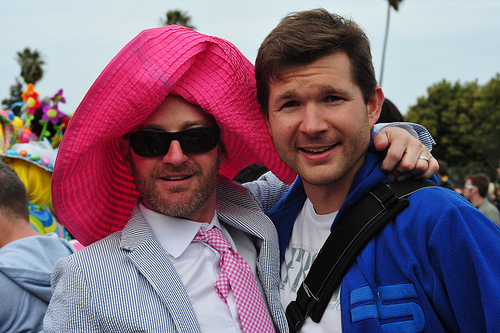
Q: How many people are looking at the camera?
A: Two.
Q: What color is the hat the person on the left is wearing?
A: Pink.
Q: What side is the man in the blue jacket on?
A: Right.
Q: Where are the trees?
A: Background.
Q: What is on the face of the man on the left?
A: Sunglasses.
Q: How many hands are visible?
A: One.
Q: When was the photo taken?
A: Daytime.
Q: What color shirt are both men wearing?
A: White.